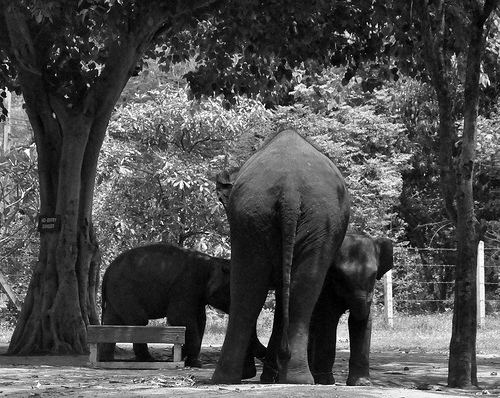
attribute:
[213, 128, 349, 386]
elephant — big, grey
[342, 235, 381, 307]
head — large, gray, wide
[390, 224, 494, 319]
fence — small, metal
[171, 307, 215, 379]
front legs — big, grey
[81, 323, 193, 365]
bar — wooden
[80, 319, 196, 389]
bench — wooden, brown, small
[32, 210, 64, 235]
sign — small, square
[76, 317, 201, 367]
wood post — little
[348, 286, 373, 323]
trunk — grey, big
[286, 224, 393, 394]
elephant — gray, large, young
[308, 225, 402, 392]
elephant — young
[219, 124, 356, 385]
elephant — adult